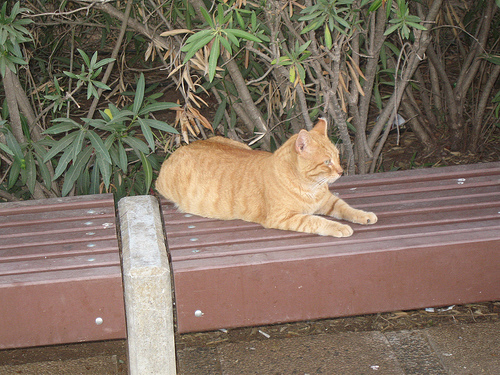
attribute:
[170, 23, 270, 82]
leaves — green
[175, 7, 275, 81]
leaves — green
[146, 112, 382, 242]
cat — brown